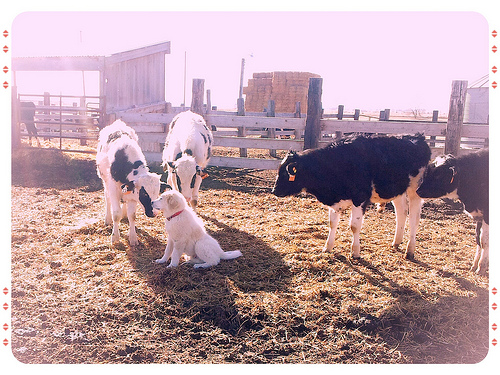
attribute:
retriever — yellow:
[150, 189, 246, 271]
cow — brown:
[93, 117, 171, 246]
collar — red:
[166, 204, 188, 225]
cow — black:
[261, 129, 435, 263]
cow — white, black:
[417, 139, 490, 275]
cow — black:
[238, 122, 435, 258]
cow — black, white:
[272, 135, 431, 257]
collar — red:
[165, 210, 185, 222]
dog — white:
[144, 187, 253, 277]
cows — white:
[87, 107, 215, 249]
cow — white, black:
[77, 114, 168, 261]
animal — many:
[150, 192, 241, 272]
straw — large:
[231, 59, 329, 129]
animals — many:
[92, 105, 486, 272]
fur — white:
[186, 223, 206, 246]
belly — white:
[368, 188, 406, 209]